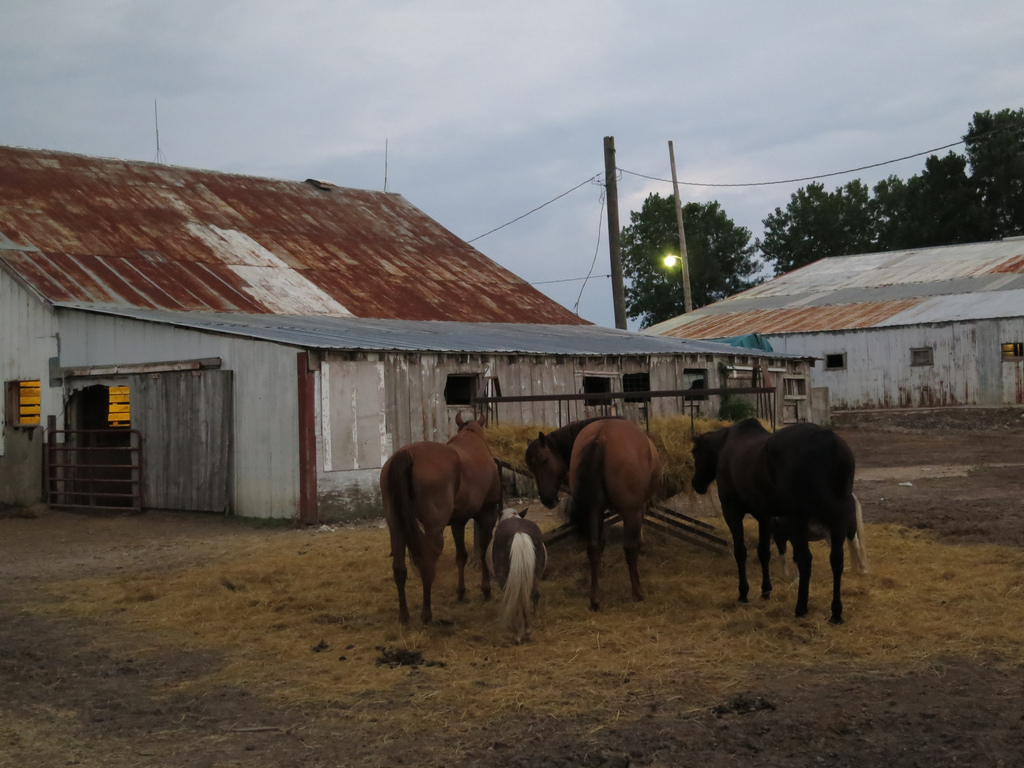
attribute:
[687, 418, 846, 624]
horse — black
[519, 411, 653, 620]
horse — brown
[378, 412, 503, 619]
horse — brown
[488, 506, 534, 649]
pony — small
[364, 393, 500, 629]
horse — brown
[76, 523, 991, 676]
hay — fresh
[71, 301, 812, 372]
roof — metal, new, unrusted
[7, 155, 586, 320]
roof — taller, rusted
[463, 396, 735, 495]
hay — fresh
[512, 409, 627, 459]
mane — black